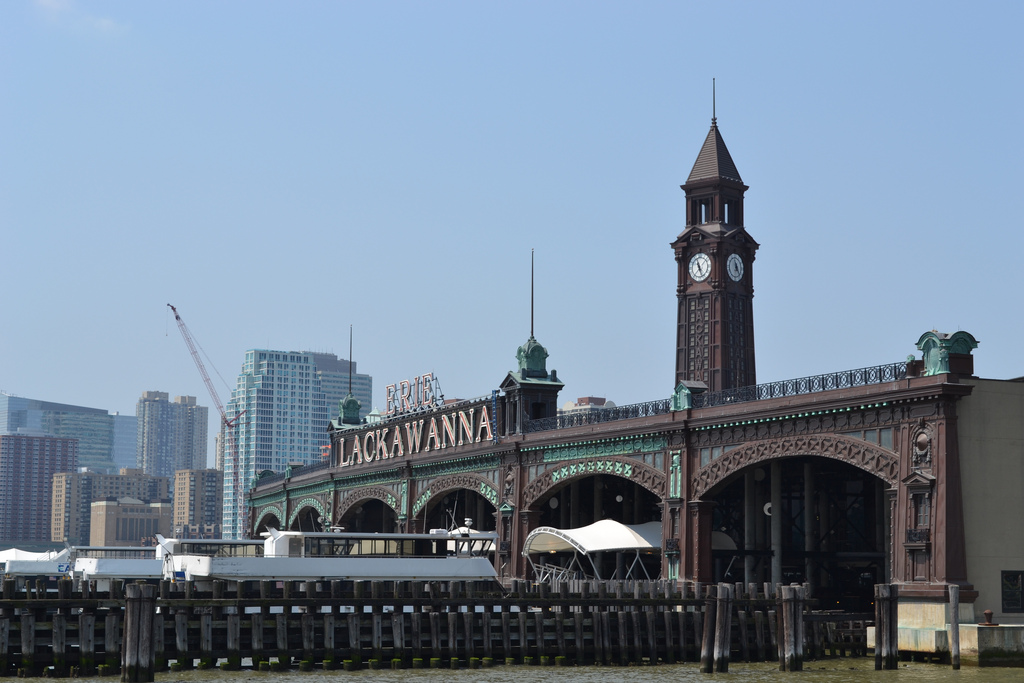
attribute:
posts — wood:
[867, 582, 894, 669]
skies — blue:
[2, 2, 1021, 375]